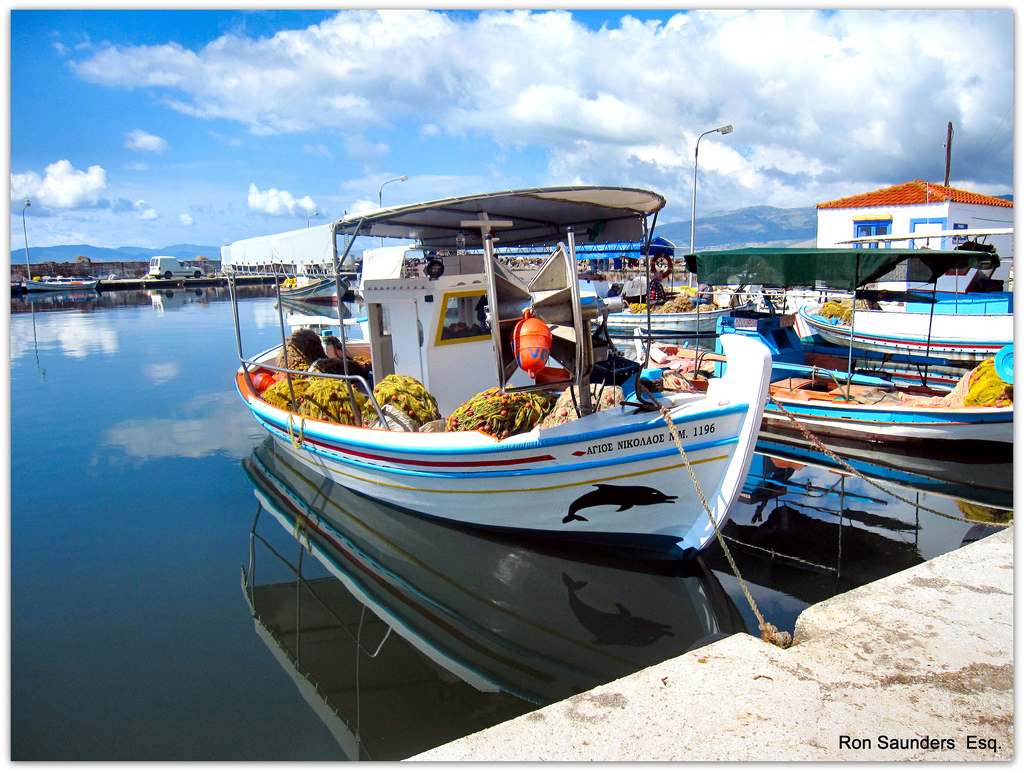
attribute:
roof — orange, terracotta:
[805, 174, 1008, 214]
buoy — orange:
[517, 307, 550, 390]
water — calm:
[19, 294, 898, 756]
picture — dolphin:
[559, 462, 692, 533]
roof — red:
[809, 165, 1009, 211]